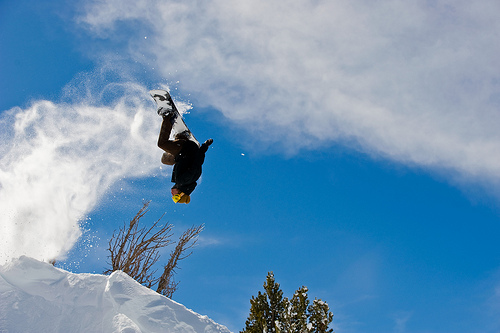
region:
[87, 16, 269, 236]
person doing flip on snowboard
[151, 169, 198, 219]
person wearing yellow knit hat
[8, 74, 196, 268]
snow flying through air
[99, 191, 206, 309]
dead weeds behind snowbank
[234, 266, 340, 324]
snow covered tree behind snowbank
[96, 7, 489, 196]
grey cloud in sky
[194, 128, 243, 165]
person wearing black gloves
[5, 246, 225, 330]
ridge of snow under snowboarder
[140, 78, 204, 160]
snowboard attached to person's feet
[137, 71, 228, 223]
person in upside down position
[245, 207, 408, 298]
Clear blue sky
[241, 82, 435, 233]
Big white cloud in sky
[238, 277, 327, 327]
Green leaves on tree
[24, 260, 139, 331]
Snow covering ground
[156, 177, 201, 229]
Yellow hat on person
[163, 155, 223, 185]
Person wearing dark jacket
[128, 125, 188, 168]
Brown pants on person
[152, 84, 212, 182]
Person is in the air upside down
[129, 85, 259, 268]
Person is snowboarding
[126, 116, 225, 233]
Person doing a trick while snowboarding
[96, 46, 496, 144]
white cloud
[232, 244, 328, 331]
top of tree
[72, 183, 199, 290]
tree branches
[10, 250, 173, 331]
snow mound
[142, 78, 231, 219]
snowboarder flipping in air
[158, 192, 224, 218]
yellow cap on snowboarders head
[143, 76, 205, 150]
snowboard with snow on it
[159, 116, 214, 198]
black outfit on snowboarder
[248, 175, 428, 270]
blue sky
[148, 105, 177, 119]
snow on black snow boots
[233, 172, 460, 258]
Sky is blue color.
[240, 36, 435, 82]
Clouds are white color.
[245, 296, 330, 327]
Plants are green color.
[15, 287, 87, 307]
Snow is white color.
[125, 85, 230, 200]
One person is doing tricks in snow boarding.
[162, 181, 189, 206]
Goggles is yellow color.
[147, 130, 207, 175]
Dress is black color.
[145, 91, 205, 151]
Snow board is black color.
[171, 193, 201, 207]
Cap is brown color.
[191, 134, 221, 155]
Gloves are black color.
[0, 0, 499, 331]
a bright blue sky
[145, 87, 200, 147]
a black and white snowboard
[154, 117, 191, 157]
the leg of a person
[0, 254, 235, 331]
a mound of snow on the ground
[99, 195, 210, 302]
a barren brown tree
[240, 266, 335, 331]
the top of a green tree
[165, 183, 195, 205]
the head of a person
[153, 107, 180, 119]
the shoe of a person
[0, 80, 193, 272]
snow powder in the air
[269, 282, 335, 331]
snow on the tree branches